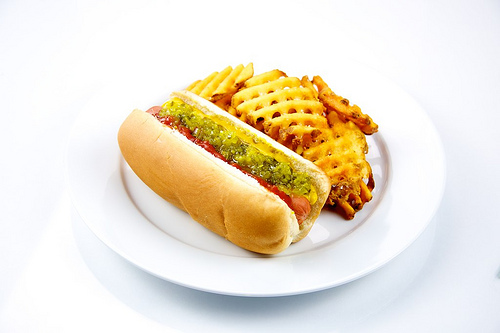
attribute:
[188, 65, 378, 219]
fries — criss cut, potato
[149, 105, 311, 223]
hot dog — bun length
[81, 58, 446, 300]
plate — white, clean, circular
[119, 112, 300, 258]
bun — white, brown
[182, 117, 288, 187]
relish toppings — green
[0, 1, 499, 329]
surface — white